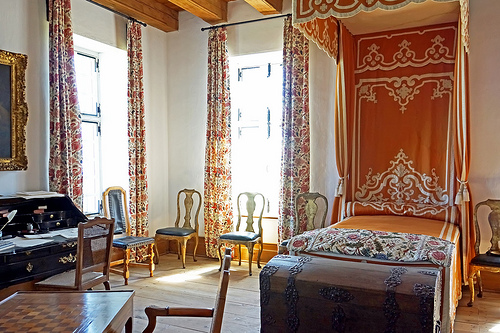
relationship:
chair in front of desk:
[201, 185, 301, 283] [6, 193, 106, 289]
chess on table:
[7, 288, 114, 330] [2, 286, 161, 333]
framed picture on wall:
[0, 39, 31, 182] [3, 9, 50, 188]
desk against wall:
[0, 192, 106, 297] [0, 3, 53, 204]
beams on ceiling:
[129, 6, 282, 31] [178, 13, 200, 41]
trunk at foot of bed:
[255, 247, 442, 332] [303, 194, 448, 326]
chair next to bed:
[465, 194, 499, 306] [283, 175, 466, 323]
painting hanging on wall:
[4, 33, 35, 185] [139, 28, 225, 225]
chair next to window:
[218, 192, 262, 274] [228, 54, 284, 213]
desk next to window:
[6, 193, 106, 289] [65, 35, 123, 192]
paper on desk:
[1, 224, 86, 251] [0, 186, 106, 288]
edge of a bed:
[430, 217, 460, 300] [279, 204, 463, 332]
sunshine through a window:
[157, 243, 233, 294] [47, 27, 142, 182]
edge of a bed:
[325, 246, 380, 256] [280, 150, 465, 330]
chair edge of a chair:
[217, 232, 254, 242] [215, 186, 269, 278]